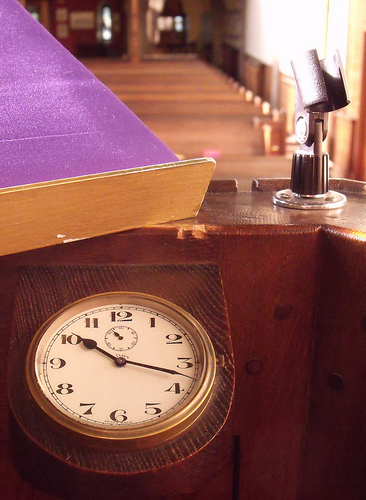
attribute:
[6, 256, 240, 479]
clock — analog, timex, wooden, brown, white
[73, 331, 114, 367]
hand — short, black, small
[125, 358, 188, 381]
hand — long, black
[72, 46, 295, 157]
pews — faded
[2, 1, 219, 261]
stand — purple, brown, small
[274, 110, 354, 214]
stand — silver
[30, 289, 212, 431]
face — white, round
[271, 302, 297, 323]
button — wooden, small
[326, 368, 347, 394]
button — wooden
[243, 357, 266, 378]
button — wooden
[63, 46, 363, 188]
floor — wooden, brown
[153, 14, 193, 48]
door — brown, large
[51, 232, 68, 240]
spot — white, tiny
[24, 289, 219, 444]
rim — gold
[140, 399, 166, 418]
number — black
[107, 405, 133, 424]
number — black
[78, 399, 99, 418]
number — black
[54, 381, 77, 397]
number — black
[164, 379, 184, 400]
number — black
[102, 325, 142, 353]
clock — small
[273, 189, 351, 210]
base — silver, round, metal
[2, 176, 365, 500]
wood — brown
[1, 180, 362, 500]
desk — wooden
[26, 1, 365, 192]
background — blurry